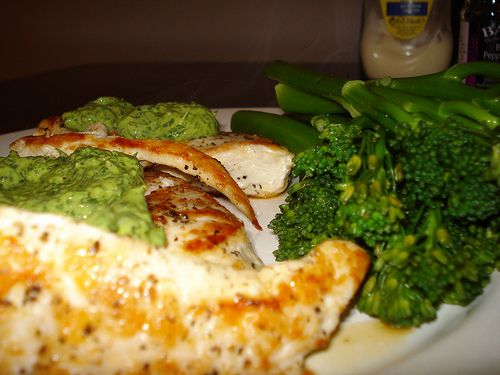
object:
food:
[0, 62, 500, 375]